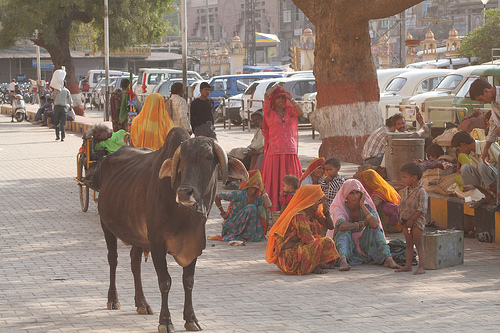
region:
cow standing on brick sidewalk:
[76, 118, 239, 331]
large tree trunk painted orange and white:
[284, 0, 439, 165]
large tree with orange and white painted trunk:
[1, 0, 174, 122]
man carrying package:
[43, 66, 77, 148]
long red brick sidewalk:
[0, 91, 496, 329]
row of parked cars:
[71, 53, 498, 155]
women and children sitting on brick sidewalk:
[210, 137, 498, 279]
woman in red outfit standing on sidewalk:
[253, 75, 315, 220]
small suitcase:
[415, 222, 476, 274]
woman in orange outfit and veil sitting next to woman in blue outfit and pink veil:
[256, 172, 403, 285]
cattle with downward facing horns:
[85, 124, 237, 331]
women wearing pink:
[254, 76, 306, 233]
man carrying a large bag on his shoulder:
[42, 57, 79, 147]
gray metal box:
[417, 224, 468, 271]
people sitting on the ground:
[262, 177, 402, 306]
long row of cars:
[70, 54, 498, 157]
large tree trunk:
[288, 0, 426, 162]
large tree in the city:
[1, 0, 172, 147]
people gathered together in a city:
[79, 2, 498, 330]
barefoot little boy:
[391, 158, 431, 283]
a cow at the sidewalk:
[68, 75, 284, 329]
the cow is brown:
[93, 101, 283, 264]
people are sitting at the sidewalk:
[178, 49, 488, 309]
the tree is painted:
[302, 15, 434, 210]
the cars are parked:
[74, 54, 489, 149]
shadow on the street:
[20, 147, 130, 309]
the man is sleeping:
[78, 120, 150, 217]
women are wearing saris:
[256, 181, 408, 281]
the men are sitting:
[416, 115, 495, 193]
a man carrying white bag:
[43, 58, 105, 188]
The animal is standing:
[77, 134, 237, 331]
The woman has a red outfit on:
[216, 63, 331, 241]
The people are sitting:
[229, 165, 489, 272]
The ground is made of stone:
[14, 178, 93, 330]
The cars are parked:
[110, 70, 485, 138]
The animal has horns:
[115, 134, 292, 221]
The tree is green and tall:
[1, 3, 191, 98]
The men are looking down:
[341, 67, 494, 169]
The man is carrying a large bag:
[28, 55, 140, 225]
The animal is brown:
[74, 150, 227, 284]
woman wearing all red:
[248, 72, 338, 236]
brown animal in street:
[72, 121, 247, 318]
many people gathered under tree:
[251, 52, 448, 290]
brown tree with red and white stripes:
[302, 34, 414, 229]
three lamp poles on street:
[15, 15, 253, 165]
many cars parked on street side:
[67, 47, 495, 179]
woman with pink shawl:
[332, 171, 406, 265]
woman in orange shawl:
[260, 184, 338, 284]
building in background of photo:
[5, 34, 67, 111]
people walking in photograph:
[11, 77, 105, 172]